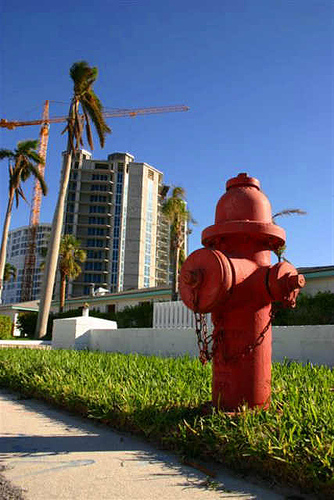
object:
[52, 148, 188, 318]
blue building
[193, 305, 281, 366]
chain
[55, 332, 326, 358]
wall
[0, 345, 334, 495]
grass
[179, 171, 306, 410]
bolt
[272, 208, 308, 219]
feather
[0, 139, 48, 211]
leaves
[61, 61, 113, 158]
top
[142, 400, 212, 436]
shadow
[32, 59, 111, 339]
palm tree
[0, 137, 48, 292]
palm tree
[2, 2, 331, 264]
sky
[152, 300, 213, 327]
fence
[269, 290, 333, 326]
shrubbery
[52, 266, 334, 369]
building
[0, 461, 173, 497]
sun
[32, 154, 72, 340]
trunk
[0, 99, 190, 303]
crane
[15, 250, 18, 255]
window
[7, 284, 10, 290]
window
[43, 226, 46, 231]
window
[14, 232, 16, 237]
window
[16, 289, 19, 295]
window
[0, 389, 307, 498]
footpath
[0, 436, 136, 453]
shadow